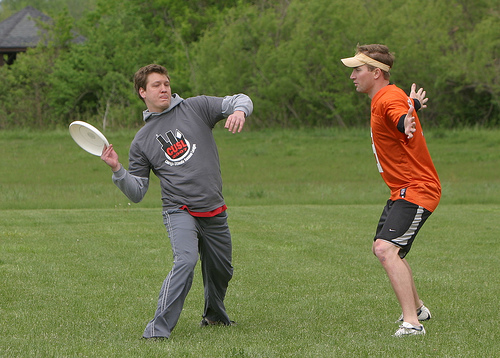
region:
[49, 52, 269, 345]
person wearing all grey clothing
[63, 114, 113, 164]
white frisbee made of plastic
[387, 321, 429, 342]
white and black shoe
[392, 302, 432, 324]
white and black shoe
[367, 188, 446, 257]
pair of black and grey shorts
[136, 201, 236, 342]
pair of grey pants with white stripe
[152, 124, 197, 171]
logo on a grey shirt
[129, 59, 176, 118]
head of a man throwing a frisbee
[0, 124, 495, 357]
the grass is short and green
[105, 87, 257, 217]
grey sweater with a hood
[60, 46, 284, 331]
he is going to toss the frisbee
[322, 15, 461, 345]
he is trying to block him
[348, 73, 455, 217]
this is an orange shirt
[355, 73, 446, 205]
an orange football jersey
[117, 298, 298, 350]
his feet are enveloped by grass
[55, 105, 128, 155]
the frisbee is white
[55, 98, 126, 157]
the flying disc is white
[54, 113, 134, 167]
the frisbee is in his right hand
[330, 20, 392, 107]
he is wearing a visor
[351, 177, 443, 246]
a pair of black and grey Nike shorts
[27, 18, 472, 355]
these guys are playing frisbee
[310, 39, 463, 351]
this man is playing defense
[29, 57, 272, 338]
this guy is playing offense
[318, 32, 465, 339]
he is wearing orange and black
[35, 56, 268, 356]
he is wearing a gray sweatsuit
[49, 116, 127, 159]
the frisbee is white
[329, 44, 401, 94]
he has on a tan visor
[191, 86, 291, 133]
his arm is bent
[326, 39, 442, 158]
his arms are spread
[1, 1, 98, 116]
a structure in hte background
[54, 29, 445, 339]
these two men are playing frisbee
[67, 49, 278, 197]
he is preparing to throw the frisbee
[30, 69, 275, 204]
his arms are bent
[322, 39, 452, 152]
he spread his arms wide to stop the frisbee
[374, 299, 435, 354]
this guy is wearing white shoes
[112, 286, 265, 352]
the man's pants is covering his shoes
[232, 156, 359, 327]
the grass is well manicured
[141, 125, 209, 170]
he has a logo on his shirt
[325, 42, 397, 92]
he is wearing a visor